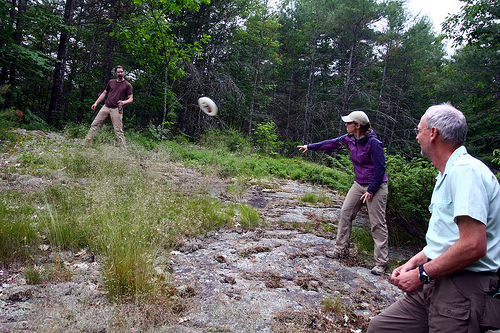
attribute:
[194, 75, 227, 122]
frisbee — white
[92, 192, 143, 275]
grass — patchy, growing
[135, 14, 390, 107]
trees — alot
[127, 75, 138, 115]
arm — outstretched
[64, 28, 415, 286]
people — standing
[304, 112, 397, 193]
jacket — purple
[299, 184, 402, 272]
pants — brown, tan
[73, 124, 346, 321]
area — rocky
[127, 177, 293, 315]
ground — rocky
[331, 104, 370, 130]
cap — baseball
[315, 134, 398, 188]
top — purple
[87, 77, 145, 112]
shirt — short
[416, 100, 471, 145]
hair — grey, gray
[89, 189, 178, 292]
weeds — tall